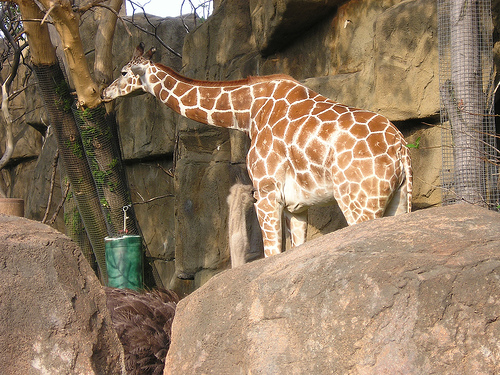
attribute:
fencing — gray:
[422, 3, 486, 220]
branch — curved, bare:
[1, 32, 21, 174]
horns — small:
[131, 38, 162, 60]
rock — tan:
[313, 17, 467, 117]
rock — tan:
[191, 21, 260, 87]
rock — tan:
[170, 129, 257, 264]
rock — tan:
[33, 32, 100, 219]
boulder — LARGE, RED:
[180, 203, 497, 353]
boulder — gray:
[144, 194, 494, 367]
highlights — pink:
[247, 290, 311, 365]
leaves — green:
[72, 99, 127, 216]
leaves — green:
[53, 67, 103, 212]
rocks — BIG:
[174, 201, 499, 372]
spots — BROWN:
[290, 97, 314, 118]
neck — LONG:
[149, 58, 255, 132]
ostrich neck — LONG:
[220, 195, 261, 262]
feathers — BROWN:
[103, 286, 181, 371]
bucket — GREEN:
[101, 225, 151, 290]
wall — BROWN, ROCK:
[317, 13, 449, 115]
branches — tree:
[128, 0, 218, 48]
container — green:
[70, 213, 199, 319]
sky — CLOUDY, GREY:
[119, 0, 214, 22]